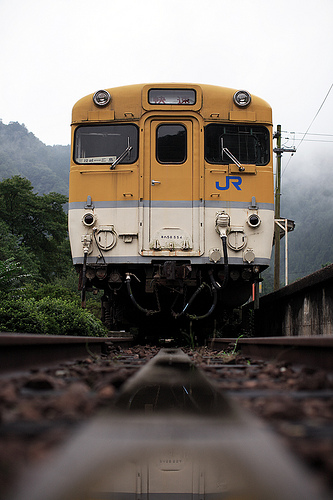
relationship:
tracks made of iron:
[3, 332, 329, 499] [2, 332, 135, 369]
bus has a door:
[67, 83, 277, 336] [146, 119, 196, 252]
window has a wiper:
[206, 123, 270, 169] [222, 147, 244, 173]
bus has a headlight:
[67, 83, 277, 336] [247, 212, 261, 229]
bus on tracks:
[67, 83, 277, 336] [3, 332, 329, 499]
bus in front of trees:
[67, 83, 277, 336] [2, 174, 107, 336]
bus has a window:
[67, 83, 277, 336] [206, 123, 270, 169]